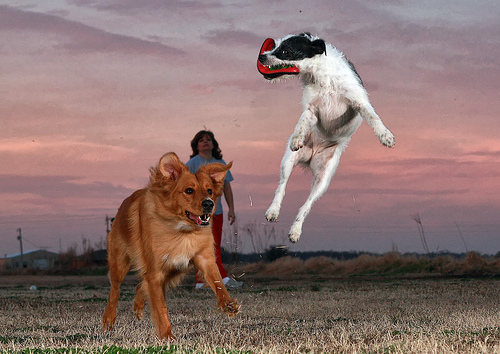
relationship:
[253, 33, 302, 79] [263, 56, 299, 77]
frisbee in mouth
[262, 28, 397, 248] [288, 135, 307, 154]
dog has paw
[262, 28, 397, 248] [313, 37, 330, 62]
dog has ear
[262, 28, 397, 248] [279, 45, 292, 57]
dog has eye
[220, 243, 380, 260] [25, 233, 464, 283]
bushes in distance